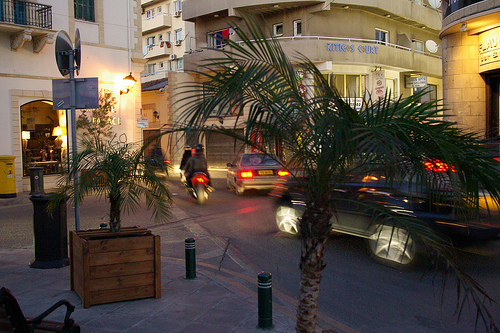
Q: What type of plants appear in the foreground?
A: Palm trees.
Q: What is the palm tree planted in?
A: A large wooden box.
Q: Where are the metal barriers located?
A: Along the left side of the street on the sidewalk in front of the palm trees.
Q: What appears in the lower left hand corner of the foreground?
A: A park bench.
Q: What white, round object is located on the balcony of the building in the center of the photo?
A: A satellite dish.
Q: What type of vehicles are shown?
A: Motorcycle and car.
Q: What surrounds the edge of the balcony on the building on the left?
A: A black, iron rail.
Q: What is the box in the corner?
A: Planter.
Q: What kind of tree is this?
A: Palm tree.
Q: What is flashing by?
A: Car.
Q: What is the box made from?
A: Wood.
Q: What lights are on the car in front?
A: Brake lights.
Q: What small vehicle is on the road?
A: Motorcycle.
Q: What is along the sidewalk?
A: Posts.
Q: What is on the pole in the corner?
A: Signs.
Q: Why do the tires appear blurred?
A: Moving car.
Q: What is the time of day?
A: Near dusk.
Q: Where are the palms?
A: In planters.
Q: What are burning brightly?
A: Brakelights.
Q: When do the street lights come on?
A: At dusk.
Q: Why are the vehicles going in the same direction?
A: A one-way-street.